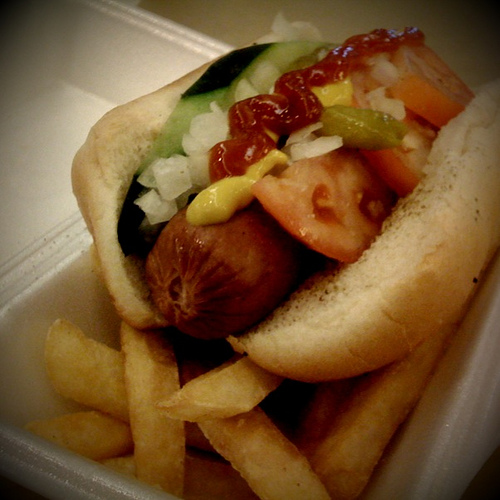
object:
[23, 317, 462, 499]
fries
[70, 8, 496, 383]
sandwich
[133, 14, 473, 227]
toppings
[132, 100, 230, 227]
onions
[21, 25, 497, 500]
food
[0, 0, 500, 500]
styrofoam box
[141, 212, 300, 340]
hot dog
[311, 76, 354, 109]
mustard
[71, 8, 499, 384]
tablehot dogs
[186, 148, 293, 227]
mustard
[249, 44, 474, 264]
ketchup